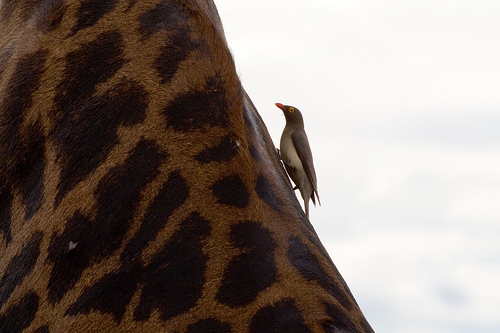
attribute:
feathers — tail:
[249, 114, 354, 215]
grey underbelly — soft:
[280, 125, 304, 170]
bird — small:
[284, 90, 342, 180]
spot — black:
[208, 172, 250, 210]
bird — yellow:
[5, 4, 433, 317]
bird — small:
[258, 81, 346, 220]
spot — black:
[280, 228, 352, 310]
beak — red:
[270, 96, 296, 122]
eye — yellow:
[281, 96, 301, 128]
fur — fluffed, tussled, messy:
[70, 68, 159, 168]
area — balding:
[202, 155, 317, 247]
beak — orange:
[267, 80, 301, 120]